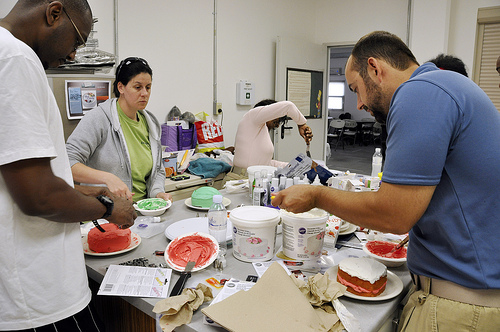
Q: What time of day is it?
A: Daytime.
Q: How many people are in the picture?
A: Four.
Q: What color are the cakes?
A: Red, green.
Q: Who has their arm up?
A: Woman.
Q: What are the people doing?
A: Decorating a cake.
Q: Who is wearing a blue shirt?
A: Man.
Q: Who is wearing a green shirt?
A: Woman.